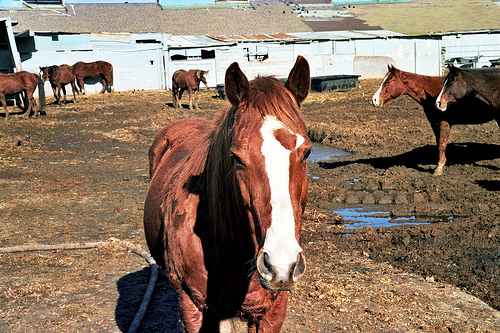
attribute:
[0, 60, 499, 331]
horses — standing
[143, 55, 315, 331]
horse — brown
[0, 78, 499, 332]
ground — brown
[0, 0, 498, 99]
stables — white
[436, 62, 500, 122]
horse — dark brown